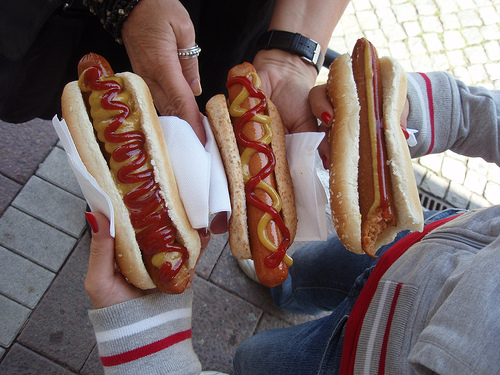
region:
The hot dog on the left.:
[73, 57, 208, 292]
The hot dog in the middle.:
[220, 57, 295, 292]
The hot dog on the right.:
[335, 41, 427, 251]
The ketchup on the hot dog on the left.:
[87, 69, 183, 275]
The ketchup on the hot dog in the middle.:
[234, 72, 294, 291]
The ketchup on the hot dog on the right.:
[367, 42, 399, 219]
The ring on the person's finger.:
[175, 43, 202, 58]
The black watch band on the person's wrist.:
[247, 32, 328, 65]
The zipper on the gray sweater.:
[422, 227, 498, 251]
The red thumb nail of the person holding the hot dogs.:
[80, 211, 102, 233]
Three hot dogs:
[59, 38, 426, 293]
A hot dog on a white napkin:
[52, 50, 214, 299]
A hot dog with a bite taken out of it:
[326, 30, 427, 257]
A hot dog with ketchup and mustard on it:
[210, 60, 299, 292]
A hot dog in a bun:
[61, 52, 201, 294]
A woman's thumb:
[82, 209, 119, 299]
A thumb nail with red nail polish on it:
[81, 209, 103, 236]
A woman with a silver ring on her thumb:
[173, 20, 206, 99]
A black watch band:
[255, 25, 327, 76]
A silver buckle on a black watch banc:
[303, 34, 324, 64]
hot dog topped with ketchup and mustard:
[59, 51, 201, 296]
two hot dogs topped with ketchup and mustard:
[58, 49, 300, 294]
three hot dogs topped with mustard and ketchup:
[51, 35, 426, 295]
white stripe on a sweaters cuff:
[404, 73, 428, 158]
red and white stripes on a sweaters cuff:
[95, 304, 193, 366]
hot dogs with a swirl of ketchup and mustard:
[58, 50, 203, 296]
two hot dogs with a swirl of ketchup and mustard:
[60, 49, 299, 296]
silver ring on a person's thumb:
[176, 43, 204, 58]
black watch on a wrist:
[257, 28, 327, 74]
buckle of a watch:
[288, 30, 322, 65]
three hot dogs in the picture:
[27, 16, 452, 302]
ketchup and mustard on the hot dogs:
[49, 24, 427, 304]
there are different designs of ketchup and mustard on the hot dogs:
[64, 20, 429, 297]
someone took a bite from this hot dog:
[316, 44, 426, 261]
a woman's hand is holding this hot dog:
[39, 154, 202, 318]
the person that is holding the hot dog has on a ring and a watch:
[166, 19, 313, 259]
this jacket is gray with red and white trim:
[333, 243, 495, 374]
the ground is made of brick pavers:
[350, 2, 492, 76]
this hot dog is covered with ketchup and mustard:
[57, 56, 203, 312]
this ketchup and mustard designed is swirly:
[212, 67, 300, 273]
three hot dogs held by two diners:
[59, 36, 424, 293]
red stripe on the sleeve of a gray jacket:
[98, 327, 193, 367]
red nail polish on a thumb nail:
[83, 211, 100, 233]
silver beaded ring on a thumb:
[173, 42, 204, 60]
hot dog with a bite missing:
[351, 36, 398, 259]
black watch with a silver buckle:
[256, 26, 326, 75]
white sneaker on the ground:
[234, 258, 257, 282]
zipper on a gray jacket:
[419, 231, 487, 252]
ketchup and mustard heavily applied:
[78, 66, 187, 285]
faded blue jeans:
[235, 207, 468, 373]